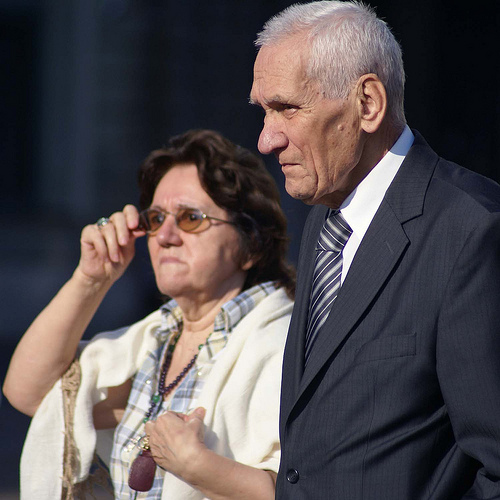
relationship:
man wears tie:
[247, 0, 500, 500] [300, 206, 358, 368]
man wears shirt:
[247, 0, 500, 500] [306, 122, 416, 282]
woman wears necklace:
[98, 113, 273, 356] [152, 311, 201, 403]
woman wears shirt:
[0, 129, 297, 500] [95, 282, 275, 498]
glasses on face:
[115, 177, 232, 239] [135, 165, 213, 303]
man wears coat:
[247, 0, 500, 500] [272, 129, 499, 498]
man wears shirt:
[247, 0, 500, 500] [337, 122, 416, 287]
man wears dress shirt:
[247, 0, 500, 500] [338, 126, 415, 287]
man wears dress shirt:
[262, 50, 452, 340] [326, 124, 415, 292]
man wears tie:
[247, 0, 500, 500] [308, 207, 372, 329]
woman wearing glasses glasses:
[0, 129, 297, 500] [141, 207, 233, 232]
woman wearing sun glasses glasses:
[0, 129, 297, 500] [139, 207, 237, 236]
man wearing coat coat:
[247, 0, 500, 500] [274, 130, 498, 499]